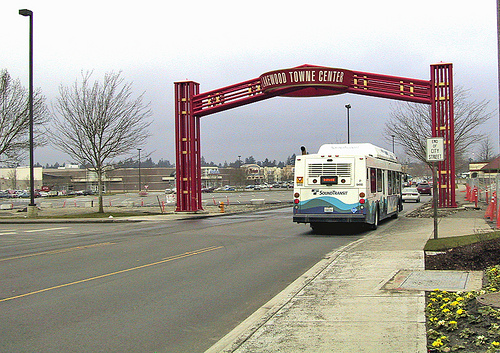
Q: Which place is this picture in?
A: It is at the road.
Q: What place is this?
A: It is a road.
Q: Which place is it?
A: It is a road.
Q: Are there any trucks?
A: No, there are no trucks.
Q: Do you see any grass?
A: Yes, there is grass.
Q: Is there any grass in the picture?
A: Yes, there is grass.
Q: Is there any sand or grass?
A: Yes, there is grass.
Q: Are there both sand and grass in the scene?
A: No, there is grass but no sand.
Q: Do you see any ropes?
A: No, there are no ropes.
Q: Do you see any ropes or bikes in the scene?
A: No, there are no ropes or bikes.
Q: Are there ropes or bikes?
A: No, there are no ropes or bikes.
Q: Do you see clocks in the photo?
A: No, there are no clocks.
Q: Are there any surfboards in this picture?
A: No, there are no surfboards.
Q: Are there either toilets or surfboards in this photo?
A: No, there are no surfboards or toilets.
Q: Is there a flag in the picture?
A: No, there are no flags.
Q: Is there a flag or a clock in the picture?
A: No, there are no flags or clocks.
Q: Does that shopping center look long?
A: Yes, the shopping center is long.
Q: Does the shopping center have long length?
A: Yes, the shopping center is long.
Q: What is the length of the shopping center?
A: The shopping center is long.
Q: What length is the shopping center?
A: The shopping center is long.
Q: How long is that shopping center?
A: The shopping center is long.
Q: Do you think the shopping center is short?
A: No, the shopping center is long.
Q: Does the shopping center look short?
A: No, the shopping center is long.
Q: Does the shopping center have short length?
A: No, the shopping center is long.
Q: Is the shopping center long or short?
A: The shopping center is long.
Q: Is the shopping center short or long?
A: The shopping center is long.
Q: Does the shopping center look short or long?
A: The shopping center is long.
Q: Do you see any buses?
A: Yes, there is a bus.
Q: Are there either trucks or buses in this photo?
A: Yes, there is a bus.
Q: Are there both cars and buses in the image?
A: Yes, there are both a bus and a car.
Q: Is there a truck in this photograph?
A: No, there are no trucks.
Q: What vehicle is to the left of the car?
A: The vehicle is a bus.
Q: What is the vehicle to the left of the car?
A: The vehicle is a bus.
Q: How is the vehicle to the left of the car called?
A: The vehicle is a bus.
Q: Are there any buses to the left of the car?
A: Yes, there is a bus to the left of the car.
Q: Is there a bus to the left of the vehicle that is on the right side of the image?
A: Yes, there is a bus to the left of the car.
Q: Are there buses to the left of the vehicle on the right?
A: Yes, there is a bus to the left of the car.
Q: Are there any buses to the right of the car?
A: No, the bus is to the left of the car.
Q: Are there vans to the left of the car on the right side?
A: No, there is a bus to the left of the car.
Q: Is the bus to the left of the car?
A: Yes, the bus is to the left of the car.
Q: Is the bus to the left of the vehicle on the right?
A: Yes, the bus is to the left of the car.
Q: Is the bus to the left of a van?
A: No, the bus is to the left of the car.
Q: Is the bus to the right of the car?
A: No, the bus is to the left of the car.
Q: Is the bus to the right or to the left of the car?
A: The bus is to the left of the car.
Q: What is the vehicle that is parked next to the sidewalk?
A: The vehicle is a bus.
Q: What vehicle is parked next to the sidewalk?
A: The vehicle is a bus.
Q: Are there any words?
A: Yes, there are words.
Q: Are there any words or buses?
A: Yes, there are words.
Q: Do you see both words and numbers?
A: No, there are words but no numbers.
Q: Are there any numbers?
A: No, there are no numbers.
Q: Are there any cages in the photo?
A: No, there are no cages.